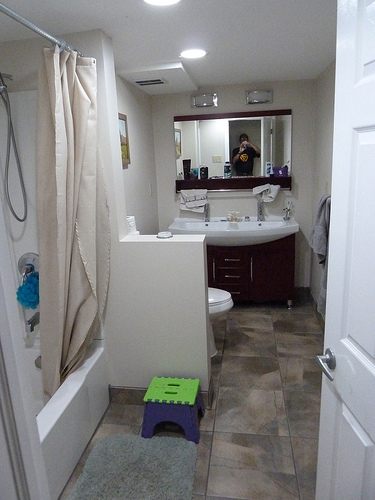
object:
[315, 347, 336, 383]
knob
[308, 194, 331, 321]
towel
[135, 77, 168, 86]
vent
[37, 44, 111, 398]
curtain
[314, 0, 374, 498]
door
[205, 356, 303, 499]
tilted floor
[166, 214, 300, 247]
sink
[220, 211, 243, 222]
toiletries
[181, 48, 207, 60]
light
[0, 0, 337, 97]
ceiling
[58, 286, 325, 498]
floor